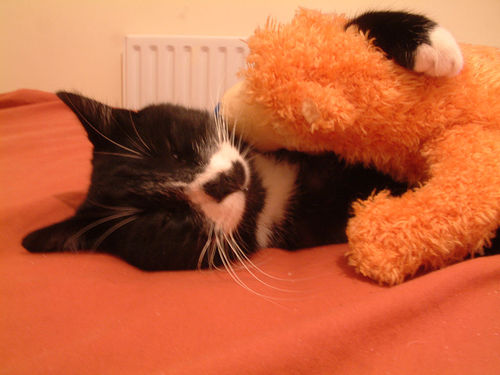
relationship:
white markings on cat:
[188, 142, 250, 235] [17, 4, 499, 310]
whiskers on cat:
[191, 222, 315, 316] [12, 4, 499, 286]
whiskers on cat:
[200, 78, 270, 163] [12, 4, 499, 286]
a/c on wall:
[123, 32, 255, 120] [10, 6, 239, 67]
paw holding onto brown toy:
[358, 9, 465, 80] [213, 5, 500, 288]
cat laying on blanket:
[17, 4, 499, 310] [179, 276, 335, 360]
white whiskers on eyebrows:
[105, 128, 152, 229] [123, 136, 156, 228]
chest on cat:
[249, 151, 340, 248] [20, 10, 496, 307]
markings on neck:
[243, 142, 308, 256] [225, 113, 314, 246]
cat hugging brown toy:
[12, 4, 499, 286] [213, 5, 500, 288]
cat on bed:
[17, 4, 499, 310] [61, 274, 243, 375]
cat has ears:
[17, 4, 499, 310] [46, 82, 109, 132]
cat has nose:
[17, 4, 499, 310] [203, 158, 248, 205]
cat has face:
[12, 4, 499, 286] [85, 100, 258, 260]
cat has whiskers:
[17, 4, 499, 310] [191, 206, 275, 301]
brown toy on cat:
[225, 5, 498, 276] [21, 81, 389, 248]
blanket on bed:
[0, 85, 499, 374] [45, 280, 157, 340]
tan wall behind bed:
[3, 3, 498, 108] [47, 283, 142, 346]